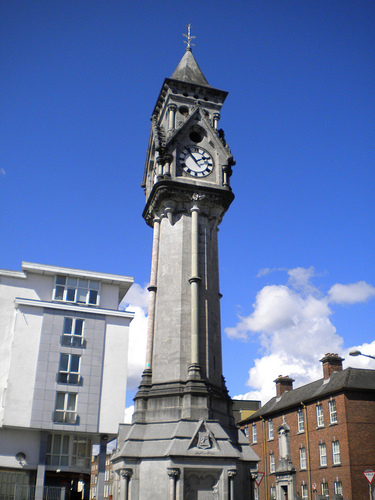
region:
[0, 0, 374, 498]
an outdoor scene of a clock tower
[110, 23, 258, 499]
a grey colored concrete clock tower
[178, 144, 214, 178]
the clock time displayed is 1:54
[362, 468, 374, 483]
a yield sign is at the corner of the street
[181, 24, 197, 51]
a weather vane at the top of the tower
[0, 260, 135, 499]
a modern building behind the clock tower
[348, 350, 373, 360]
a street light over the public street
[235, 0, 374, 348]
blue sky with low puffy white clouds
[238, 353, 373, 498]
a brown brick building behind the clock tower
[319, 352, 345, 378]
a brick chimney on top of the brick building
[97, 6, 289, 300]
a clock face on a tower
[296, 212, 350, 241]
the sky is blue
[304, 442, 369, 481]
the windows are white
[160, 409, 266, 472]
a grey decorative brick triangle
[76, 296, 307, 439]
modern and old buildings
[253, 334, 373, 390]
two chimneys in brick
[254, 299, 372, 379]
the sky is cloudy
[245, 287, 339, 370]
the clouds are white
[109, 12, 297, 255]
the clockface is white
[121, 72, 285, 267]
the numbers are roman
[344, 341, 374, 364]
the top of a street lamp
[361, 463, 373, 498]
a triangular yield sign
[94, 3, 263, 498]
a stone clock tower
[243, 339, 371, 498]
a three story brick building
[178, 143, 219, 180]
a clock face that says 1:55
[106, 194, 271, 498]
stone base of a statue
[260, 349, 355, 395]
brick chimneys with nothing coming out of them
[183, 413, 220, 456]
carved triangular design in stone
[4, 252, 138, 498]
modern multi-story building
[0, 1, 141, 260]
clear blue sky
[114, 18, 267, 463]
This is a simple clock tower.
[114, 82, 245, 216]
The tower has four faces.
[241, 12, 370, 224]
The sky is a rich blue.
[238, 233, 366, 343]
A few clouds are showing.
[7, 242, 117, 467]
There are buildings in the background.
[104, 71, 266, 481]
The clock tower is stone.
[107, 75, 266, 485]
It is a grey clock tower.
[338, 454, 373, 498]
There is a yield sign.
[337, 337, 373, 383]
A street lamp can be seen.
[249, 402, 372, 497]
This is a brick building.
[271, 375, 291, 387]
chimney top on red brick building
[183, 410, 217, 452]
over the clock tower door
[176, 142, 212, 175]
clock face on clock tower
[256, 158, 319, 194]
sky besides the clock face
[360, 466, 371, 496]
traffic sign by brick building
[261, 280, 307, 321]
cloud beside the clock tower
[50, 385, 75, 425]
window in gray building behind clock tower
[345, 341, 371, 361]
street light by red brick building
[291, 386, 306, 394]
part of roof on red brick building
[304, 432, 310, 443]
part of gutter on red brick building